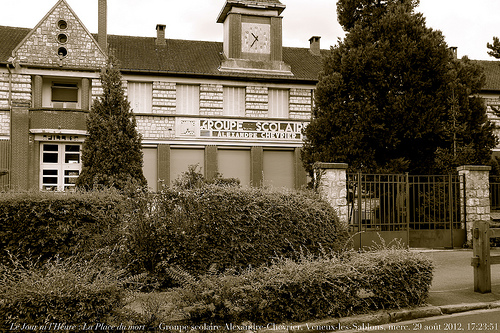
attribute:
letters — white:
[202, 121, 305, 145]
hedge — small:
[12, 220, 417, 290]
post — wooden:
[473, 221, 498, 297]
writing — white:
[9, 319, 498, 332]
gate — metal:
[345, 162, 471, 249]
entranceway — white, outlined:
[35, 136, 82, 188]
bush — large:
[0, 186, 145, 271]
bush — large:
[18, 151, 338, 290]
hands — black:
[247, 26, 262, 49]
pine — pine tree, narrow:
[77, 50, 149, 191]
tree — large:
[303, 1, 495, 213]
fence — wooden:
[324, 149, 494, 260]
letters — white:
[193, 116, 302, 144]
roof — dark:
[119, 33, 224, 76]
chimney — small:
[152, 21, 169, 44]